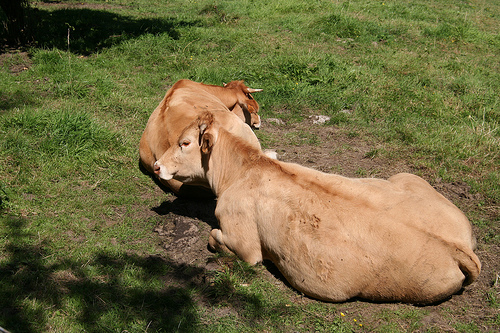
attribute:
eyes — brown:
[177, 132, 195, 150]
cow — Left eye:
[136, 65, 484, 313]